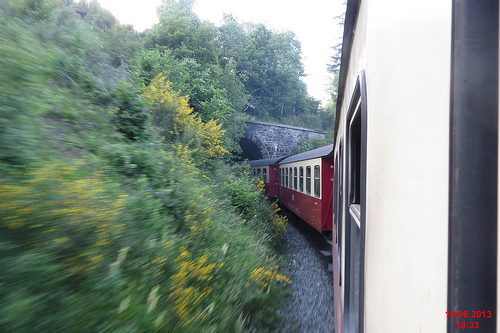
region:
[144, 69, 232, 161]
yellow flowers on a hill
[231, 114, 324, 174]
stone arch of train tunnel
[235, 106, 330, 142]
bridge over train tracks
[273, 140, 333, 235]
red and white train car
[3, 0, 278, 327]
green bushes next to train track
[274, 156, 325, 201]
white window frame on train car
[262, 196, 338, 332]
gravel next to track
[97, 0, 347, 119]
sky peeking through trees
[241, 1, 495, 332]
train entering tunnel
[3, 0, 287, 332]
steep hillside next to train track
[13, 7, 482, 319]
train traveling through a forestry area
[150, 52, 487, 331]
train going through a tunnel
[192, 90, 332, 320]
red railroad train cars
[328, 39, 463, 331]
white and gray train car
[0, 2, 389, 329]
shrubbery and trees next to a railway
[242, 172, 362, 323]
gravel alongside a railway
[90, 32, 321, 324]
yellow flowers within shrubbery and trees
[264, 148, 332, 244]
white window trimming around railroad train windows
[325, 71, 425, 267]
open window on railway car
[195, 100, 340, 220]
brick tunnel over the railroad car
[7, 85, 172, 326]
picture is blurry in places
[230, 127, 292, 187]
going through a dark tunnel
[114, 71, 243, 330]
green bushes and yellow flowers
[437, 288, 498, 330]
time/date stamp on photo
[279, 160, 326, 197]
train car has windows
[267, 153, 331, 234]
train car has red and white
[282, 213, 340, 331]
gravel on the side of train tracks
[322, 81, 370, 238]
train window is open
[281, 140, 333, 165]
roof of train is black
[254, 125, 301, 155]
tunnel is made of stone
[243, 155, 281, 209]
red and white train car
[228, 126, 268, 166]
train coming out of tunnel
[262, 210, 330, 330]
rocks alongside train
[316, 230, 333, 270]
stairs on side of train car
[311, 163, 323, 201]
window on train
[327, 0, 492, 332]
white train car in front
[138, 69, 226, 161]
yellow plants on hill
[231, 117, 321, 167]
tunnel made of bricks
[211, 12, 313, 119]
trees above brick tunnel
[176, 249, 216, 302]
yellow flowers grow atop bushes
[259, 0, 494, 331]
a trains is entering a tunnel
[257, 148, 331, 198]
two train cars are red with white trimmed windows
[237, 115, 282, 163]
a dark tunnel looms ahead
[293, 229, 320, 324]
gravel is on the ground next the tracks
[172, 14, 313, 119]
trees tower over a bridge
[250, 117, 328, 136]
a brick bridge sits over a tunnel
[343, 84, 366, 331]
a open window on a train caboose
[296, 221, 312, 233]
railroad tracks support a speeding train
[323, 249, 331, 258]
a metal step protrudes on the side of the train